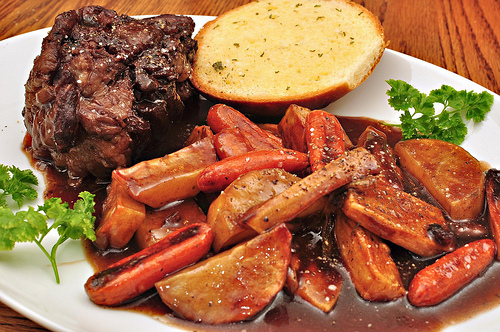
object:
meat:
[21, 5, 196, 187]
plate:
[0, 15, 447, 332]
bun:
[189, 0, 389, 118]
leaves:
[381, 78, 493, 145]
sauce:
[18, 96, 499, 331]